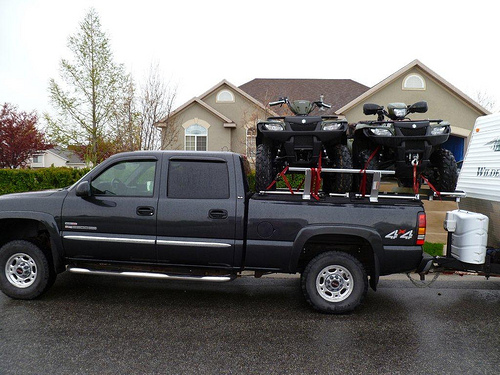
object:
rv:
[441, 110, 499, 277]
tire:
[301, 247, 367, 314]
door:
[63, 199, 157, 266]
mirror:
[73, 176, 95, 198]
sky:
[127, 7, 384, 75]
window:
[166, 158, 231, 201]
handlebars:
[267, 93, 336, 118]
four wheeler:
[1, 149, 378, 324]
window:
[181, 119, 212, 152]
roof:
[238, 70, 373, 125]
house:
[148, 59, 495, 199]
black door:
[62, 156, 159, 272]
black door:
[158, 151, 238, 282]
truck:
[0, 151, 425, 316]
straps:
[314, 163, 351, 186]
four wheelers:
[250, 92, 352, 193]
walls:
[185, 71, 485, 197]